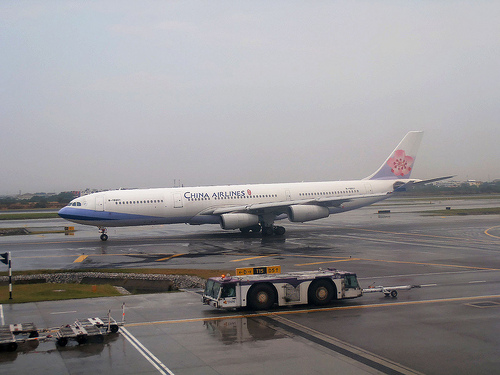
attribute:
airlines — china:
[50, 117, 447, 272]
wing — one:
[195, 185, 390, 245]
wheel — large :
[244, 277, 278, 315]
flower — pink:
[387, 150, 414, 179]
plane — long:
[56, 130, 454, 240]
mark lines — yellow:
[379, 265, 499, 351]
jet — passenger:
[58, 128, 451, 240]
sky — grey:
[0, 3, 497, 198]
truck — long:
[194, 261, 429, 313]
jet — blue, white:
[52, 125, 459, 249]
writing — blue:
[182, 189, 247, 199]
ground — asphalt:
[431, 252, 464, 352]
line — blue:
[57, 211, 119, 222]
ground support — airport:
[196, 260, 373, 330]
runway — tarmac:
[1, 199, 498, 372]